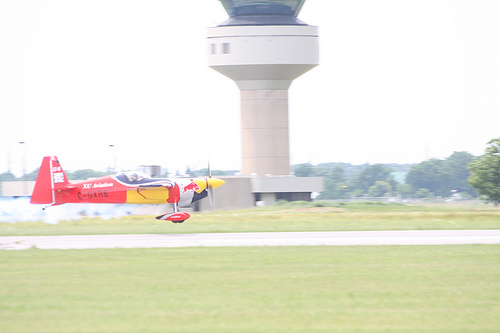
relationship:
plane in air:
[30, 155, 225, 223] [3, 4, 499, 225]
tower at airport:
[203, 1, 325, 205] [0, 139, 499, 332]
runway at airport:
[1, 231, 499, 251] [0, 139, 499, 332]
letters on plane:
[77, 192, 109, 200] [30, 155, 225, 223]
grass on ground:
[1, 200, 497, 333] [1, 205, 499, 332]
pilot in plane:
[130, 173, 137, 183] [30, 155, 225, 223]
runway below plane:
[1, 231, 499, 251] [30, 155, 225, 223]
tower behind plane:
[203, 1, 325, 205] [30, 155, 225, 223]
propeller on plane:
[205, 160, 223, 204] [30, 155, 225, 223]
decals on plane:
[53, 155, 115, 200] [30, 155, 225, 223]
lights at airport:
[17, 142, 117, 199] [0, 139, 499, 332]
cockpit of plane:
[117, 171, 152, 185] [30, 155, 225, 223]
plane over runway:
[30, 155, 225, 223] [1, 231, 499, 251]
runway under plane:
[1, 231, 499, 251] [30, 155, 225, 223]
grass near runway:
[1, 200, 497, 333] [1, 231, 499, 251]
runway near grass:
[1, 231, 499, 251] [1, 200, 497, 333]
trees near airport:
[293, 138, 499, 204] [0, 139, 499, 332]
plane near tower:
[30, 155, 225, 223] [203, 1, 325, 205]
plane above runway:
[30, 155, 225, 223] [1, 231, 499, 251]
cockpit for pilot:
[117, 171, 152, 185] [130, 173, 137, 183]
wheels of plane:
[171, 219, 184, 224] [30, 155, 225, 223]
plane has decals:
[30, 155, 225, 223] [53, 155, 115, 200]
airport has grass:
[0, 139, 499, 332] [1, 200, 497, 333]